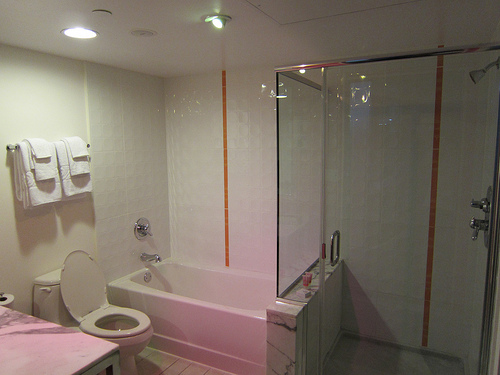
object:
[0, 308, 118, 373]
countertop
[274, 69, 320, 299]
divider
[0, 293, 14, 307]
paper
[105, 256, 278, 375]
bathtub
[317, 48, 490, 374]
door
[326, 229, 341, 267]
handle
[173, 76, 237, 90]
tiles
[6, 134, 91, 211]
white towels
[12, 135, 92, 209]
towels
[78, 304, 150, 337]
seat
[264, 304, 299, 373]
wall tile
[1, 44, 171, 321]
wall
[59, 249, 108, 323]
lid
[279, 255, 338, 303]
shelf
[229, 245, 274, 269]
tile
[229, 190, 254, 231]
tile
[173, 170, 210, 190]
tile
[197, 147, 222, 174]
tile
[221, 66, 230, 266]
line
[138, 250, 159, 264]
tub fixtures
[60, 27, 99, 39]
light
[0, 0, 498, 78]
ceiling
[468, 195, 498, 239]
valves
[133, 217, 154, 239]
handle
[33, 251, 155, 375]
toilet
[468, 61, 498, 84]
shower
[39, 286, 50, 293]
handle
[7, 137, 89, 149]
rack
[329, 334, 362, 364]
tile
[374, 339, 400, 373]
tile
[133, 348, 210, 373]
tile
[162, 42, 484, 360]
wall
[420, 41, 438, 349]
stripe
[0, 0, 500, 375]
bathroom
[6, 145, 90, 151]
bar